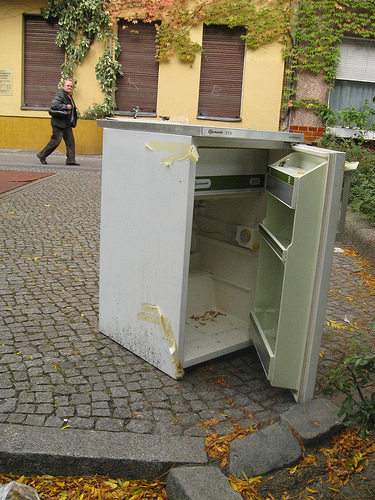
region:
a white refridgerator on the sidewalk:
[88, 102, 329, 398]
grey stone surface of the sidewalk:
[51, 364, 151, 416]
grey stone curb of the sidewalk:
[24, 433, 130, 483]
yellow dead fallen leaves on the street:
[58, 475, 135, 498]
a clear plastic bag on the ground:
[0, 476, 43, 498]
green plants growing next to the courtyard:
[350, 159, 374, 209]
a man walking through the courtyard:
[29, 71, 91, 174]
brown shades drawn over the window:
[194, 28, 245, 123]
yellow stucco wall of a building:
[250, 48, 267, 117]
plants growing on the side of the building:
[78, 0, 285, 48]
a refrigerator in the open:
[33, 64, 337, 338]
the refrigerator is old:
[85, 106, 345, 387]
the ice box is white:
[77, 122, 345, 387]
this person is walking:
[24, 69, 81, 170]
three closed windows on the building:
[13, 9, 265, 131]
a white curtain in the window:
[319, 25, 373, 139]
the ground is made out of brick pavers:
[21, 360, 350, 485]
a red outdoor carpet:
[5, 163, 67, 224]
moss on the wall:
[245, 8, 321, 123]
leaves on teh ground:
[37, 400, 361, 498]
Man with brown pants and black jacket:
[31, 69, 84, 168]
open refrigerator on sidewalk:
[87, 95, 348, 397]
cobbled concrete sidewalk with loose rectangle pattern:
[8, 223, 88, 403]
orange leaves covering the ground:
[33, 470, 164, 498]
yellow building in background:
[5, 10, 293, 153]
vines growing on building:
[39, 1, 368, 85]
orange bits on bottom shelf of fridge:
[189, 307, 234, 328]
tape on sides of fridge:
[131, 126, 199, 387]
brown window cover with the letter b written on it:
[199, 20, 247, 125]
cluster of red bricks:
[291, 119, 330, 143]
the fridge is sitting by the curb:
[94, 104, 351, 416]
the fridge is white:
[126, 186, 152, 226]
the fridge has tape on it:
[135, 299, 173, 344]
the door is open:
[284, 143, 334, 402]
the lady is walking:
[41, 73, 86, 171]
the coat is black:
[56, 95, 64, 107]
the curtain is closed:
[337, 86, 367, 109]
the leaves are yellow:
[84, 481, 107, 498]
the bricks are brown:
[307, 125, 318, 140]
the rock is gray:
[187, 471, 217, 496]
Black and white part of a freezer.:
[161, 172, 201, 194]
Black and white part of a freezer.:
[48, 408, 73, 434]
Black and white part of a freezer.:
[285, 445, 317, 476]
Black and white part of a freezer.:
[103, 9, 164, 118]